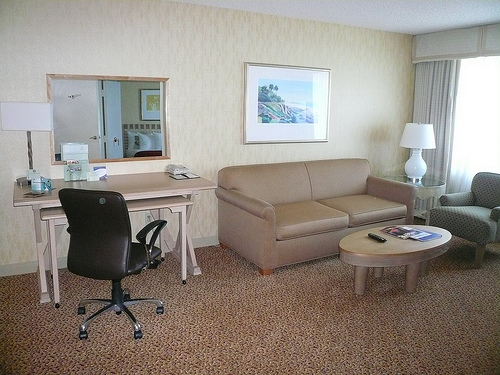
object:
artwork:
[241, 60, 328, 143]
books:
[381, 223, 414, 239]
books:
[405, 226, 442, 241]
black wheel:
[134, 329, 143, 339]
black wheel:
[155, 305, 165, 315]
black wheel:
[79, 330, 88, 341]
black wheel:
[75, 305, 86, 314]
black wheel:
[122, 293, 131, 300]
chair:
[429, 171, 497, 267]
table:
[387, 177, 446, 226]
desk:
[10, 170, 213, 305]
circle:
[98, 197, 106, 204]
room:
[0, 7, 500, 375]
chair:
[58, 187, 167, 337]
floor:
[0, 240, 497, 372]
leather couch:
[213, 158, 419, 275]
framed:
[47, 72, 171, 165]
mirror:
[45, 72, 172, 164]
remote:
[368, 230, 388, 243]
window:
[447, 54, 496, 189]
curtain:
[403, 57, 461, 215]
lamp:
[398, 122, 436, 180]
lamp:
[1, 103, 55, 184]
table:
[338, 222, 452, 295]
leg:
[258, 266, 273, 277]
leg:
[219, 241, 228, 251]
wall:
[0, 0, 417, 283]